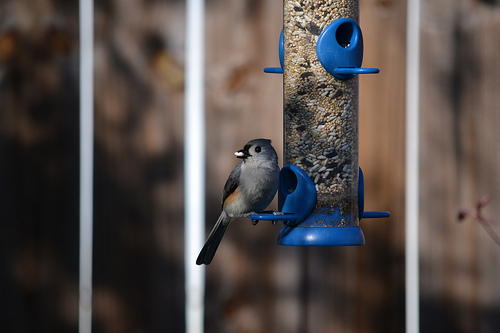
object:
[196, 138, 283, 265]
bird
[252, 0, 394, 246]
feeder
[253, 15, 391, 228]
trays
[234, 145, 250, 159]
beak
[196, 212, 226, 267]
tail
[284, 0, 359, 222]
seed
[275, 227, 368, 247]
bottom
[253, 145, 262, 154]
eye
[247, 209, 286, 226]
feet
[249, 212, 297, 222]
perch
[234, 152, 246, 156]
seed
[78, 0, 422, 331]
fence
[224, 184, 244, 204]
orange patch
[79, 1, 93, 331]
pole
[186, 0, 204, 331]
pole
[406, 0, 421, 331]
pole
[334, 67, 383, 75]
perch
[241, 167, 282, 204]
chest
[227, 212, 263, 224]
leg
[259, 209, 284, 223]
leg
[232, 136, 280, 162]
head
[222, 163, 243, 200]
wing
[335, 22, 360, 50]
hole